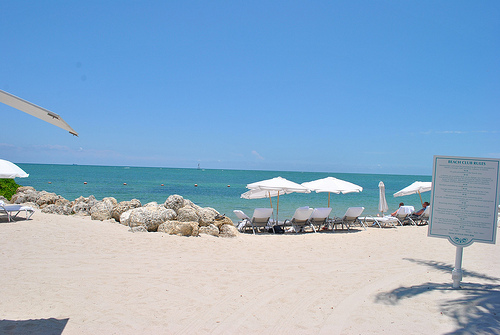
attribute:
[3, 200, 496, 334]
sand — brown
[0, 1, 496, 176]
sky — blue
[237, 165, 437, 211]
umbrellas — white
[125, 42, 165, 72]
clouds — white